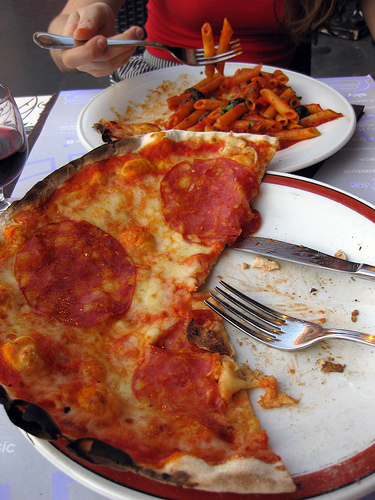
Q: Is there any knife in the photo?
A: Yes, there is a knife.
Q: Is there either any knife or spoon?
A: Yes, there is a knife.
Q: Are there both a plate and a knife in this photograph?
A: Yes, there are both a knife and a plate.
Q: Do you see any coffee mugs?
A: No, there are no coffee mugs.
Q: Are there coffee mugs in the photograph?
A: No, there are no coffee mugs.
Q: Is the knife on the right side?
A: Yes, the knife is on the right of the image.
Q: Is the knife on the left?
A: No, the knife is on the right of the image.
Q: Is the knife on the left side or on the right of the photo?
A: The knife is on the right of the image.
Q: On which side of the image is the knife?
A: The knife is on the right of the image.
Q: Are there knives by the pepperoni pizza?
A: Yes, there is a knife by the pizza.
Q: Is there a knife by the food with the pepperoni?
A: Yes, there is a knife by the pizza.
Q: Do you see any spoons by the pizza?
A: No, there is a knife by the pizza.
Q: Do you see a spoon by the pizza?
A: No, there is a knife by the pizza.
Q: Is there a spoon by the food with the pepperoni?
A: No, there is a knife by the pizza.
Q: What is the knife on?
A: The knife is on the plate.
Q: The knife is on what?
A: The knife is on the plate.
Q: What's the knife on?
A: The knife is on the plate.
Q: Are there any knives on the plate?
A: Yes, there is a knife on the plate.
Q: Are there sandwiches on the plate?
A: No, there is a knife on the plate.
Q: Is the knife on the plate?
A: Yes, the knife is on the plate.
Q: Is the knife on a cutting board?
A: No, the knife is on the plate.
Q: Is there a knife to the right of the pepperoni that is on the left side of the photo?
A: Yes, there is a knife to the right of the pepperoni.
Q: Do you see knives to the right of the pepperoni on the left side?
A: Yes, there is a knife to the right of the pepperoni.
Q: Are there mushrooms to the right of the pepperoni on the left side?
A: No, there is a knife to the right of the pepperoni.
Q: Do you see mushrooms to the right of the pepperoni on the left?
A: No, there is a knife to the right of the pepperoni.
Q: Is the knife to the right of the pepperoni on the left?
A: Yes, the knife is to the right of the pepperoni.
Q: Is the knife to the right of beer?
A: No, the knife is to the right of the pepperoni.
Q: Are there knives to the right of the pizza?
A: Yes, there is a knife to the right of the pizza.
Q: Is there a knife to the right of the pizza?
A: Yes, there is a knife to the right of the pizza.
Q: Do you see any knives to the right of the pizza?
A: Yes, there is a knife to the right of the pizza.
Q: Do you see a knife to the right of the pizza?
A: Yes, there is a knife to the right of the pizza.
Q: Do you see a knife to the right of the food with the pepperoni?
A: Yes, there is a knife to the right of the pizza.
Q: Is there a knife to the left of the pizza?
A: No, the knife is to the right of the pizza.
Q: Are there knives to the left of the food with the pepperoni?
A: No, the knife is to the right of the pizza.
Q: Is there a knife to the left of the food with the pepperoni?
A: No, the knife is to the right of the pizza.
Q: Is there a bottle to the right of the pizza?
A: No, there is a knife to the right of the pizza.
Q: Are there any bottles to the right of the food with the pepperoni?
A: No, there is a knife to the right of the pizza.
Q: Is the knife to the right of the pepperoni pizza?
A: Yes, the knife is to the right of the pizza.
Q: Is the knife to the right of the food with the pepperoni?
A: Yes, the knife is to the right of the pizza.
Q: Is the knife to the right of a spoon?
A: No, the knife is to the right of the pizza.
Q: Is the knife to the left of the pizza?
A: No, the knife is to the right of the pizza.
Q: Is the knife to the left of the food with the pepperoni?
A: No, the knife is to the right of the pizza.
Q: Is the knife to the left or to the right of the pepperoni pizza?
A: The knife is to the right of the pizza.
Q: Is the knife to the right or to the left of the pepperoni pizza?
A: The knife is to the right of the pizza.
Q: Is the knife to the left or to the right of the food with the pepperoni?
A: The knife is to the right of the pizza.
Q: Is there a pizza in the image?
A: Yes, there is a pizza.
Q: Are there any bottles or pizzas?
A: Yes, there is a pizza.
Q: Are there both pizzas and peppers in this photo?
A: No, there is a pizza but no peppers.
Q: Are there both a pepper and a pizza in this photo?
A: No, there is a pizza but no peppers.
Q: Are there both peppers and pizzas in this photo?
A: No, there is a pizza but no peppers.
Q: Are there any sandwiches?
A: No, there are no sandwiches.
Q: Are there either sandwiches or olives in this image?
A: No, there are no sandwiches or olives.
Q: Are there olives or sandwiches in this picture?
A: No, there are no sandwiches or olives.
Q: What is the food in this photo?
A: The food is a pizza.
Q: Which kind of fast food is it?
A: The food is a pizza.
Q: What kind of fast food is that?
A: This is a pizza.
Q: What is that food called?
A: This is a pizza.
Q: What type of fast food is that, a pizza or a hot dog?
A: This is a pizza.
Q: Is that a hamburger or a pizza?
A: That is a pizza.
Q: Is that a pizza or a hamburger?
A: That is a pizza.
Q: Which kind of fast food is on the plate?
A: The food is a pizza.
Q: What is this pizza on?
A: The pizza is on the plate.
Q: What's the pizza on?
A: The pizza is on the plate.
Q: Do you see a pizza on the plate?
A: Yes, there is a pizza on the plate.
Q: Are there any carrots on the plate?
A: No, there is a pizza on the plate.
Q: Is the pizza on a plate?
A: Yes, the pizza is on a plate.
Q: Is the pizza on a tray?
A: No, the pizza is on a plate.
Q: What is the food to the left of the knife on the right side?
A: The food is a pizza.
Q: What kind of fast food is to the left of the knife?
A: The food is a pizza.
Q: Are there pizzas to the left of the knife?
A: Yes, there is a pizza to the left of the knife.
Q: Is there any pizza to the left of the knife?
A: Yes, there is a pizza to the left of the knife.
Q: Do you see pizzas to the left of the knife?
A: Yes, there is a pizza to the left of the knife.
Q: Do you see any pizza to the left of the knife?
A: Yes, there is a pizza to the left of the knife.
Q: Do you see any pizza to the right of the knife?
A: No, the pizza is to the left of the knife.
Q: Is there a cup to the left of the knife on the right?
A: No, there is a pizza to the left of the knife.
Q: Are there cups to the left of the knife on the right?
A: No, there is a pizza to the left of the knife.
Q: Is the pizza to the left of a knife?
A: Yes, the pizza is to the left of a knife.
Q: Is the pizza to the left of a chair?
A: No, the pizza is to the left of a knife.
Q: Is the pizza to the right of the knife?
A: No, the pizza is to the left of the knife.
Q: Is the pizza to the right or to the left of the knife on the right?
A: The pizza is to the left of the knife.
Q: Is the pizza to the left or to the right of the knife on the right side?
A: The pizza is to the left of the knife.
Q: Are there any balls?
A: No, there are no balls.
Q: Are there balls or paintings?
A: No, there are no balls or paintings.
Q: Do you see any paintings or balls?
A: No, there are no balls or paintings.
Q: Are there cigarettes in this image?
A: No, there are no cigarettes.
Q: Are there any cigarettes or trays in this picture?
A: No, there are no cigarettes or trays.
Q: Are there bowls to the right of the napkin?
A: No, the bowl is to the left of the napkin.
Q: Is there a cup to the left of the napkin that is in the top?
A: No, there is a bowl to the left of the napkin.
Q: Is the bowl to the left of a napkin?
A: Yes, the bowl is to the left of a napkin.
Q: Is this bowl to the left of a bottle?
A: No, the bowl is to the left of a napkin.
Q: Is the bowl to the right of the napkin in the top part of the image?
A: No, the bowl is to the left of the napkin.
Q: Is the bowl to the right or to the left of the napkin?
A: The bowl is to the left of the napkin.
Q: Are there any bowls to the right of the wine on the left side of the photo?
A: Yes, there is a bowl to the right of the wine.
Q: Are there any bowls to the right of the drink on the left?
A: Yes, there is a bowl to the right of the wine.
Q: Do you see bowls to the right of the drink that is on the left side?
A: Yes, there is a bowl to the right of the wine.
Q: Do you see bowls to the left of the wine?
A: No, the bowl is to the right of the wine.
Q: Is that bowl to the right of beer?
A: No, the bowl is to the right of the wine.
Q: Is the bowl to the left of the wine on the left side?
A: No, the bowl is to the right of the wine.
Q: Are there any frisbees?
A: No, there are no frisbees.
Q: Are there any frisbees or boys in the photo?
A: No, there are no frisbees or boys.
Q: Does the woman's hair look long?
A: Yes, the hair is long.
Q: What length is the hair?
A: The hair is long.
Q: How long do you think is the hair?
A: The hair is long.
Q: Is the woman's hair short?
A: No, the hair is long.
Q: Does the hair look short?
A: No, the hair is long.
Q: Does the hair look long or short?
A: The hair is long.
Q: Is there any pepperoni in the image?
A: Yes, there is pepperoni.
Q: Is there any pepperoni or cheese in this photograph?
A: Yes, there is pepperoni.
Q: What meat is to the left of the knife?
A: The meat is pepperoni.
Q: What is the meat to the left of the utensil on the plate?
A: The meat is pepperoni.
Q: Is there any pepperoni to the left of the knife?
A: Yes, there is pepperoni to the left of the knife.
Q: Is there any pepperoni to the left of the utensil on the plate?
A: Yes, there is pepperoni to the left of the knife.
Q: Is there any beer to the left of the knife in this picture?
A: No, there is pepperoni to the left of the knife.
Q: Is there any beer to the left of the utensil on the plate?
A: No, there is pepperoni to the left of the knife.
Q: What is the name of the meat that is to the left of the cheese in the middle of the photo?
A: The meat is pepperoni.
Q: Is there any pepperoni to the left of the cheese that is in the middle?
A: Yes, there is pepperoni to the left of the cheese.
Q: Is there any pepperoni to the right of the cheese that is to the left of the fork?
A: No, the pepperoni is to the left of the cheese.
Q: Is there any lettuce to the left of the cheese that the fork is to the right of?
A: No, there is pepperoni to the left of the cheese.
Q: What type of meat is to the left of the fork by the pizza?
A: The meat is pepperoni.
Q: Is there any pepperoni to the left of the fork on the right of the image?
A: Yes, there is pepperoni to the left of the fork.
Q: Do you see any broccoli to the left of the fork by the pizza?
A: No, there is pepperoni to the left of the fork.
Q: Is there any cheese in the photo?
A: Yes, there is cheese.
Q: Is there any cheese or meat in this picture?
A: Yes, there is cheese.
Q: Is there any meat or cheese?
A: Yes, there is cheese.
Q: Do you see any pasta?
A: Yes, there is pasta.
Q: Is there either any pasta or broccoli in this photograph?
A: Yes, there is pasta.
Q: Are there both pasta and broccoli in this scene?
A: No, there is pasta but no broccoli.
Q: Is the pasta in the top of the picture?
A: Yes, the pasta is in the top of the image.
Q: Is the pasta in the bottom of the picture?
A: No, the pasta is in the top of the image.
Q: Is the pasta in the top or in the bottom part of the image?
A: The pasta is in the top of the image.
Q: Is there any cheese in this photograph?
A: Yes, there is cheese.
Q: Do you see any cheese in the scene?
A: Yes, there is cheese.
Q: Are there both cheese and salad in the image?
A: No, there is cheese but no salad.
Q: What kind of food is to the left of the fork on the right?
A: The food is cheese.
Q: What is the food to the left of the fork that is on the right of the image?
A: The food is cheese.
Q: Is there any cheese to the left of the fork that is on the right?
A: Yes, there is cheese to the left of the fork.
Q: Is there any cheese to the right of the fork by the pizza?
A: No, the cheese is to the left of the fork.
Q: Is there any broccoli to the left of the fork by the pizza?
A: No, there is cheese to the left of the fork.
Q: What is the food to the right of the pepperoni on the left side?
A: The food is cheese.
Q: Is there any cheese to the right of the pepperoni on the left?
A: Yes, there is cheese to the right of the pepperoni.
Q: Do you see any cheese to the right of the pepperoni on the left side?
A: Yes, there is cheese to the right of the pepperoni.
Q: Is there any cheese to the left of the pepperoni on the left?
A: No, the cheese is to the right of the pepperoni.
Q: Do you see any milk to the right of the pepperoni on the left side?
A: No, there is cheese to the right of the pepperoni.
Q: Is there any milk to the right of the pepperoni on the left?
A: No, there is cheese to the right of the pepperoni.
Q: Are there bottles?
A: No, there are no bottles.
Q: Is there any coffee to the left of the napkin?
A: No, there is meal to the left of the napkin.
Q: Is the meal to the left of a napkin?
A: Yes, the meal is to the left of a napkin.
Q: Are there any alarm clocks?
A: No, there are no alarm clocks.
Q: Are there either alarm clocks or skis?
A: No, there are no alarm clocks or skis.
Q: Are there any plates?
A: Yes, there is a plate.